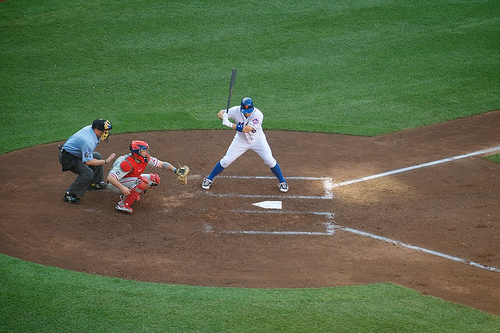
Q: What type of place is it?
A: It is a field.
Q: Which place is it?
A: It is a field.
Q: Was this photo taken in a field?
A: Yes, it was taken in a field.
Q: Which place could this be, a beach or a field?
A: It is a field.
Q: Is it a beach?
A: No, it is a field.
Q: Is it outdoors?
A: Yes, it is outdoors.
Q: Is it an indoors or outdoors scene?
A: It is outdoors.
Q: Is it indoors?
A: No, it is outdoors.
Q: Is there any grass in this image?
A: Yes, there is grass.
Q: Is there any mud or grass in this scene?
A: Yes, there is grass.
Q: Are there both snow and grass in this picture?
A: No, there is grass but no snow.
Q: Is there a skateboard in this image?
A: No, there are no skateboards.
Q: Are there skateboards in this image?
A: No, there are no skateboards.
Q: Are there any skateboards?
A: No, there are no skateboards.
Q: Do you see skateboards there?
A: No, there are no skateboards.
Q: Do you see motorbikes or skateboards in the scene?
A: No, there are no skateboards or motorbikes.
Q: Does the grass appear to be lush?
A: Yes, the grass is lush.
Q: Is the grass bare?
A: No, the grass is lush.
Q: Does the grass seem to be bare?
A: No, the grass is lush.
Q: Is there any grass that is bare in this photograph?
A: No, there is grass but it is lush.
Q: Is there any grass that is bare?
A: No, there is grass but it is lush.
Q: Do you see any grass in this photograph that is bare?
A: No, there is grass but it is lush.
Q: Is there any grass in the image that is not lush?
A: No, there is grass but it is lush.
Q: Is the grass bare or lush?
A: The grass is lush.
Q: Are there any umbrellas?
A: No, there are no umbrellas.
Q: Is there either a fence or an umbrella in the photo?
A: No, there are no umbrellas or fences.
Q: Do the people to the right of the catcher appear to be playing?
A: Yes, the people are playing.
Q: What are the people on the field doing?
A: The people are playing.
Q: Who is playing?
A: The people are playing.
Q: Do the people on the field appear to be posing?
A: No, the people are playing.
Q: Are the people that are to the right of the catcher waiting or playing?
A: The people are playing.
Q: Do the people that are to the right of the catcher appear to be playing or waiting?
A: The people are playing.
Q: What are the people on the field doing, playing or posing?
A: The people are playing.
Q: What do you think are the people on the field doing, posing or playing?
A: The people are playing.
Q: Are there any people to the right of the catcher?
A: Yes, there are people to the right of the catcher.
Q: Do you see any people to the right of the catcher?
A: Yes, there are people to the right of the catcher.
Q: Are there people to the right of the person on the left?
A: Yes, there are people to the right of the catcher.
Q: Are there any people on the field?
A: Yes, there are people on the field.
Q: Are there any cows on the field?
A: No, there are people on the field.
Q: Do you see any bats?
A: Yes, there is a bat.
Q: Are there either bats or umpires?
A: Yes, there is a bat.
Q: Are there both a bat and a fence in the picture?
A: No, there is a bat but no fences.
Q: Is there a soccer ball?
A: No, there are no soccer balls.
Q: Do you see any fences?
A: No, there are no fences.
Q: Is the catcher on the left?
A: Yes, the catcher is on the left of the image.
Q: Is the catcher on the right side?
A: No, the catcher is on the left of the image.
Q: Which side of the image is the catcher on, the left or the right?
A: The catcher is on the left of the image.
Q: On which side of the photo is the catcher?
A: The catcher is on the left of the image.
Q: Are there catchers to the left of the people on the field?
A: Yes, there is a catcher to the left of the people.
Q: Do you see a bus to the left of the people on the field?
A: No, there is a catcher to the left of the people.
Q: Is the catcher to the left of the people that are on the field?
A: Yes, the catcher is to the left of the people.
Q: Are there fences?
A: No, there are no fences.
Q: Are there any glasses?
A: No, there are no glasses.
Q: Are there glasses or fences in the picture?
A: No, there are no glasses or fences.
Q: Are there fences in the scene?
A: No, there are no fences.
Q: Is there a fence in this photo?
A: No, there are no fences.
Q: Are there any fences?
A: No, there are no fences.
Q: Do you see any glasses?
A: No, there are no glasses.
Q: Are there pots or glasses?
A: No, there are no glasses or pots.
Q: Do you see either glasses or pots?
A: No, there are no glasses or pots.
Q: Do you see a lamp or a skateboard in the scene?
A: No, there are no skateboards or lamps.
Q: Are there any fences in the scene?
A: No, there are no fences.